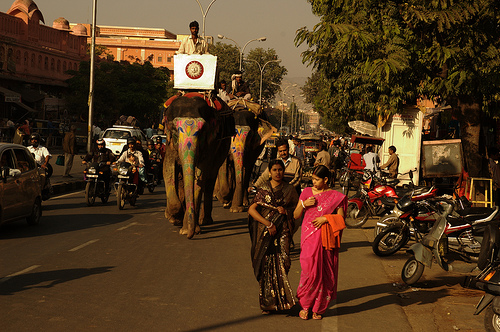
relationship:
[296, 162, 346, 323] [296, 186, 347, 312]
woman in clothing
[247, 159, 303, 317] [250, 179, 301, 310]
woman in clothing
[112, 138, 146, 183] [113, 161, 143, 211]
person riding motorcycle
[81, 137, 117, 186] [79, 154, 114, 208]
person riding motorcycle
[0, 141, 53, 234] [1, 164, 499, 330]
vehicle in street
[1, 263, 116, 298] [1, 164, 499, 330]
shadow on street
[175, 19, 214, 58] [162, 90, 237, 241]
man riding elephant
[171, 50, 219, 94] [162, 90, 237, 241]
basket on elephant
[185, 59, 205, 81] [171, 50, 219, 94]
design on basket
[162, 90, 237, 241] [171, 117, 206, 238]
elephant with trunk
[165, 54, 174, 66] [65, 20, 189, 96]
window on building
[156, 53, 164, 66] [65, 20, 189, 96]
window on building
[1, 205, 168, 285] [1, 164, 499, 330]
line on street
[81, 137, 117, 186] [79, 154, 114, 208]
person on motorcycle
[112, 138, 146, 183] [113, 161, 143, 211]
person on motorcycle